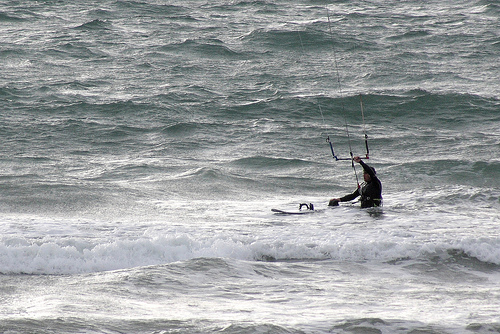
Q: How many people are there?
A: One.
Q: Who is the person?
A: A man.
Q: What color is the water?
A: Green.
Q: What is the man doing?
A: Surfing.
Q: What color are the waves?
A: White.